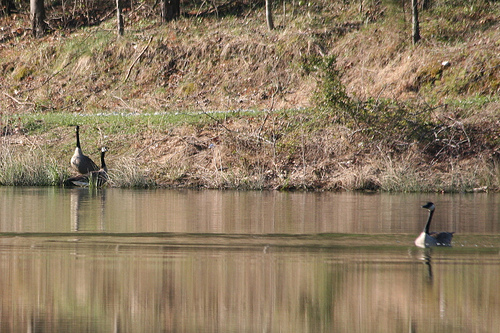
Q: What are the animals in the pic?
A: Canadian geese.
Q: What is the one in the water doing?
A: Swimming.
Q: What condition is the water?
A: Calm.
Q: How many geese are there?
A: 3.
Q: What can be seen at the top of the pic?
A: Tree trunks.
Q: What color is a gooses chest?
A: White.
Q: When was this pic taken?
A: During the day.